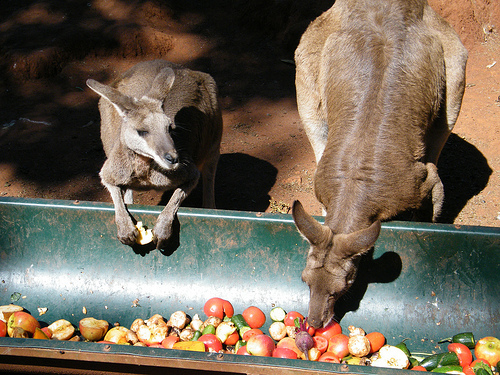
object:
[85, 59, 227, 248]
kangaroo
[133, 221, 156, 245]
fruit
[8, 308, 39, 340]
fruit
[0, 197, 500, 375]
tub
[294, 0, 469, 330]
kangaroo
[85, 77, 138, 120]
ears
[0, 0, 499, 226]
dirt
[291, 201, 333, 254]
ears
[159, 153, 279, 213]
shadow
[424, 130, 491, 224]
shadow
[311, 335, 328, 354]
tomato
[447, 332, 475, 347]
zucchini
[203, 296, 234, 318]
veggies